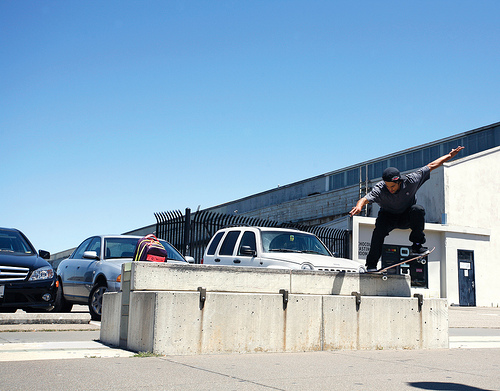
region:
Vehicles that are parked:
[1, 226, 368, 315]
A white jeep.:
[197, 218, 369, 277]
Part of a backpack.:
[131, 232, 163, 262]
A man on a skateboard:
[349, 140, 464, 275]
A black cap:
[381, 166, 403, 185]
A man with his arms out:
[340, 130, 462, 262]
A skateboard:
[366, 250, 437, 279]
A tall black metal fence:
[151, 210, 350, 267]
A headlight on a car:
[29, 263, 54, 283]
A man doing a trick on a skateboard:
[353, 140, 463, 272]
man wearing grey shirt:
[371, 188, 384, 196]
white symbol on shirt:
[398, 186, 415, 198]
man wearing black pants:
[378, 215, 390, 226]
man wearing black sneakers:
[409, 240, 431, 256]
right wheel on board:
[419, 257, 427, 264]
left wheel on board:
[377, 273, 389, 281]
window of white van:
[258, 229, 335, 256]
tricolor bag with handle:
[135, 233, 171, 262]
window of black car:
[0, 227, 35, 256]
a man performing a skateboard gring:
[347, 142, 465, 272]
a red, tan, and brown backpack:
[132, 229, 169, 264]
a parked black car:
[2, 223, 60, 314]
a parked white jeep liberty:
[198, 222, 373, 280]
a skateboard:
[368, 243, 438, 281]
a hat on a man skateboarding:
[378, 164, 405, 185]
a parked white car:
[55, 233, 197, 323]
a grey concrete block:
[1, 307, 94, 329]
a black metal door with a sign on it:
[455, 242, 477, 307]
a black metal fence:
[152, 205, 352, 265]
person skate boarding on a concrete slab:
[343, 155, 458, 289]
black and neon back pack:
[133, 220, 166, 295]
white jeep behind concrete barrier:
[213, 208, 370, 280]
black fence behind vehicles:
[141, 203, 342, 260]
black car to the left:
[10, 232, 57, 302]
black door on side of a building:
[454, 236, 479, 315]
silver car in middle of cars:
[70, 219, 172, 312]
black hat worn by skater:
[374, 151, 402, 194]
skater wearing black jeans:
[363, 179, 436, 261]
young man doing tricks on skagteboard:
[341, 137, 438, 288]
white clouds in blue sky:
[41, 33, 76, 58]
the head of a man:
[372, 166, 405, 199]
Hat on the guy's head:
[372, 160, 412, 200]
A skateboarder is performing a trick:
[335, 135, 475, 286]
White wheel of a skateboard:
[371, 265, 391, 286]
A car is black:
[0, 220, 72, 320]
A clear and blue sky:
[0, 0, 495, 255]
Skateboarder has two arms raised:
[346, 130, 473, 225]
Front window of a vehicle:
[251, 220, 336, 260]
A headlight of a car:
[20, 255, 57, 290]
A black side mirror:
[230, 235, 260, 260]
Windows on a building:
[323, 115, 496, 195]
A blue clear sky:
[1, 0, 497, 255]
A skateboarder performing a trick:
[345, 131, 471, 286]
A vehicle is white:
[195, 215, 372, 280]